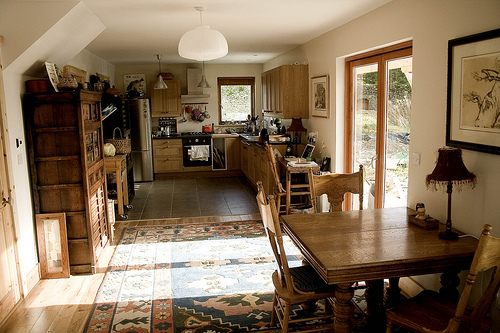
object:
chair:
[255, 180, 336, 333]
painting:
[444, 29, 500, 155]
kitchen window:
[217, 77, 255, 126]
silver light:
[153, 54, 168, 90]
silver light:
[197, 61, 209, 88]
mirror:
[43, 218, 61, 272]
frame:
[34, 211, 71, 280]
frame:
[309, 75, 332, 119]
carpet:
[122, 219, 260, 332]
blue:
[168, 298, 211, 309]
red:
[150, 273, 173, 330]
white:
[114, 309, 147, 324]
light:
[177, 25, 228, 62]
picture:
[35, 212, 70, 279]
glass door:
[380, 53, 411, 208]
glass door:
[351, 61, 378, 210]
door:
[334, 39, 412, 208]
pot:
[202, 125, 212, 133]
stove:
[182, 132, 212, 145]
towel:
[188, 144, 210, 161]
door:
[182, 137, 212, 167]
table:
[258, 163, 499, 333]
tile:
[142, 178, 238, 215]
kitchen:
[117, 61, 326, 204]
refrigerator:
[106, 98, 154, 182]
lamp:
[424, 147, 477, 242]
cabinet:
[21, 89, 114, 274]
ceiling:
[79, 0, 392, 65]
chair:
[307, 164, 365, 214]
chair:
[384, 223, 499, 332]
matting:
[463, 45, 472, 53]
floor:
[0, 279, 70, 333]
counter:
[240, 137, 306, 199]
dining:
[279, 206, 480, 333]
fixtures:
[176, 7, 228, 63]